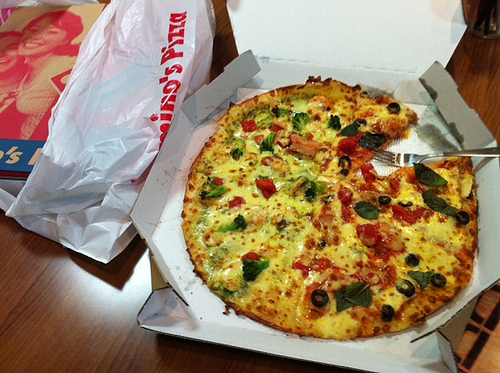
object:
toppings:
[274, 229, 406, 317]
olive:
[337, 155, 351, 166]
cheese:
[194, 84, 474, 339]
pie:
[182, 76, 479, 341]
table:
[0, 0, 500, 372]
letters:
[161, 48, 184, 65]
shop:
[0, 0, 500, 373]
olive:
[395, 280, 415, 298]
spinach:
[354, 201, 378, 220]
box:
[128, 0, 498, 373]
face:
[18, 17, 66, 55]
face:
[0, 34, 20, 72]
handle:
[422, 147, 500, 160]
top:
[225, 1, 467, 95]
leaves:
[335, 282, 372, 312]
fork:
[373, 147, 500, 168]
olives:
[387, 102, 400, 114]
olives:
[379, 196, 391, 204]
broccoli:
[242, 257, 269, 281]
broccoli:
[201, 176, 227, 198]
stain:
[413, 123, 459, 153]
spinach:
[408, 271, 436, 290]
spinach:
[412, 163, 447, 187]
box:
[0, 3, 212, 202]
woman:
[0, 10, 84, 139]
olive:
[381, 304, 394, 322]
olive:
[311, 289, 329, 307]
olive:
[405, 254, 419, 267]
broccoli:
[259, 133, 277, 154]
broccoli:
[217, 214, 247, 233]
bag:
[0, 0, 215, 264]